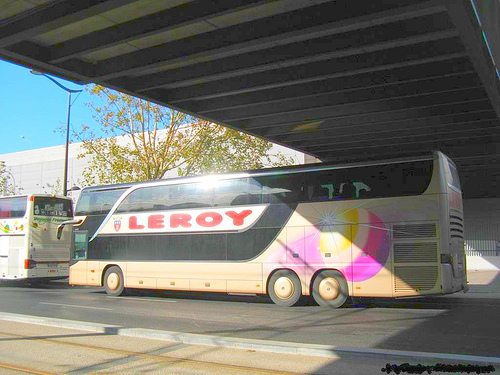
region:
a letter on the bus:
[120, 212, 142, 233]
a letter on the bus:
[141, 206, 166, 239]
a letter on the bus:
[169, 211, 192, 237]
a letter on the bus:
[195, 210, 227, 230]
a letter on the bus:
[224, 200, 253, 236]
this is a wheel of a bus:
[266, 266, 306, 311]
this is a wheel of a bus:
[305, 267, 356, 312]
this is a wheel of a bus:
[95, 257, 125, 294]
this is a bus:
[59, 143, 478, 298]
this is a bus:
[0, 191, 77, 276]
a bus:
[68, 178, 459, 294]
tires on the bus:
[264, 273, 297, 306]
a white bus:
[2, 194, 73, 277]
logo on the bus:
[121, 208, 251, 233]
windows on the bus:
[258, 173, 388, 199]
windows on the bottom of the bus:
[129, 237, 226, 259]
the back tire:
[314, 270, 354, 305]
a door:
[70, 233, 87, 260]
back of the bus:
[35, 198, 54, 276]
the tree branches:
[124, 130, 207, 168]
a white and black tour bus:
[54, 152, 468, 301]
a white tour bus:
[0, 193, 72, 283]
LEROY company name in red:
[124, 208, 253, 230]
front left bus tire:
[100, 262, 124, 296]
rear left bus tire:
[267, 265, 301, 307]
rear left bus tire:
[310, 270, 348, 310]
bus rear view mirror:
[53, 216, 84, 241]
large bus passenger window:
[73, 190, 113, 213]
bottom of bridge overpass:
[0, 0, 498, 169]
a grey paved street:
[2, 279, 498, 362]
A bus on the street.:
[43, 175, 487, 312]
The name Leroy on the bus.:
[107, 201, 259, 250]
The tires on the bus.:
[95, 258, 365, 318]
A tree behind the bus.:
[71, 93, 231, 180]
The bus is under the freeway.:
[61, 63, 478, 314]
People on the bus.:
[304, 180, 384, 205]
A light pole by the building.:
[26, 70, 84, 223]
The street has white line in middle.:
[43, 277, 168, 325]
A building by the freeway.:
[6, 131, 271, 201]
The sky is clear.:
[20, 88, 119, 139]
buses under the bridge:
[2, 17, 498, 345]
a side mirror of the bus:
[53, 222, 65, 242]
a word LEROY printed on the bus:
[123, 205, 256, 235]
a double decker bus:
[65, 148, 471, 309]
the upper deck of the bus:
[76, 154, 451, 216]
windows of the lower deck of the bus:
[86, 229, 272, 264]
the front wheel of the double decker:
[100, 260, 129, 300]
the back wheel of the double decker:
[306, 265, 351, 313]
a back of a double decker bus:
[21, 193, 73, 276]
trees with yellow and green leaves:
[97, 110, 173, 165]